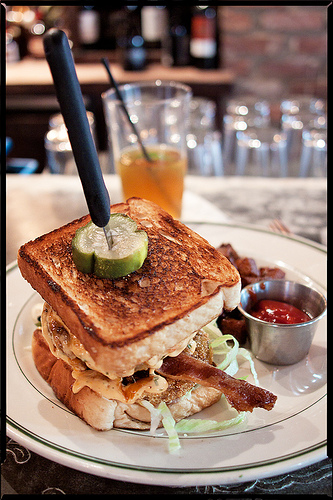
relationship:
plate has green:
[6, 217, 327, 487] [6, 220, 327, 476]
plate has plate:
[6, 217, 327, 487] [6, 217, 327, 487]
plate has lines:
[6, 217, 327, 487] [7, 217, 330, 485]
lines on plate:
[7, 217, 330, 485] [6, 217, 327, 487]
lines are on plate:
[7, 217, 330, 485] [6, 217, 327, 487]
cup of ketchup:
[236, 281, 328, 367] [238, 281, 310, 325]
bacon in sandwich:
[157, 352, 278, 412] [20, 196, 279, 452]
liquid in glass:
[119, 145, 187, 222] [101, 80, 193, 223]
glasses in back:
[48, 92, 327, 177] [50, 95, 327, 176]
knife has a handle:
[43, 28, 113, 251] [42, 28, 112, 227]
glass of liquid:
[101, 80, 193, 223] [119, 145, 187, 222]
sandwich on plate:
[20, 196, 279, 452] [6, 217, 327, 487]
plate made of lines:
[6, 217, 327, 487] [7, 217, 330, 485]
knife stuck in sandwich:
[43, 28, 113, 251] [20, 196, 279, 452]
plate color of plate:
[6, 217, 327, 487] [6, 217, 327, 487]